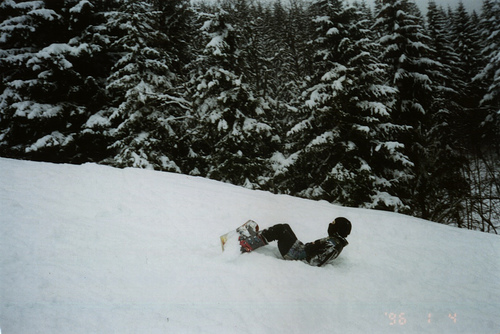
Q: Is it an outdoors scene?
A: Yes, it is outdoors.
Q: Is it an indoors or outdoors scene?
A: It is outdoors.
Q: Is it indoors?
A: No, it is outdoors.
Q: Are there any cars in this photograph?
A: No, there are no cars.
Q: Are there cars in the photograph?
A: No, there are no cars.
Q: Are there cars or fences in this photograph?
A: No, there are no cars or fences.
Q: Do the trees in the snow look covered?
A: Yes, the trees are covered.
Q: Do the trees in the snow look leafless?
A: No, the trees are covered.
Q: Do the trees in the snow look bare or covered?
A: The trees are covered.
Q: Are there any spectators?
A: No, there are no spectators.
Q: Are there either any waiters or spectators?
A: No, there are no spectators or waiters.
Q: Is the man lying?
A: Yes, the man is lying.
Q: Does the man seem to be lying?
A: Yes, the man is lying.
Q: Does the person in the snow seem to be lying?
A: Yes, the man is lying.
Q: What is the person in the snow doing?
A: The man is lying.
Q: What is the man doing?
A: The man is lying.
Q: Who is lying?
A: The man is lying.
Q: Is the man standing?
A: No, the man is lying.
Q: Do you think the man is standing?
A: No, the man is lying.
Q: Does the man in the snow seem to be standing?
A: No, the man is lying.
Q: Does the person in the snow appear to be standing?
A: No, the man is lying.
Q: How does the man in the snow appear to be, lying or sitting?
A: The man is lying.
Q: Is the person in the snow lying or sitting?
A: The man is lying.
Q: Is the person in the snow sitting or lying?
A: The man is lying.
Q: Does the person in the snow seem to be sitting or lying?
A: The man is lying.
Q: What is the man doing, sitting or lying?
A: The man is lying.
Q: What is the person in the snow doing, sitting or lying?
A: The man is lying.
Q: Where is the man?
A: The man is in the snow.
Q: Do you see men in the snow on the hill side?
A: Yes, there is a man in the snow.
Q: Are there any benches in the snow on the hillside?
A: No, there is a man in the snow.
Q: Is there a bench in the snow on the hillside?
A: No, there is a man in the snow.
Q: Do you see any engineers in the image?
A: No, there are no engineers.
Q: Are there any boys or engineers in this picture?
A: No, there are no engineers or boys.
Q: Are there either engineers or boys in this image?
A: No, there are no engineers or boys.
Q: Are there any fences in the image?
A: No, there are no fences.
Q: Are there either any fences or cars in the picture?
A: No, there are no fences or cars.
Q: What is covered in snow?
A: The tree is covered in snow.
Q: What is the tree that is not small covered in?
A: The tree is covered in snow.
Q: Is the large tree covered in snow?
A: Yes, the tree is covered in snow.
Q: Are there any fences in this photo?
A: No, there are no fences.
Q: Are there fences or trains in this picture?
A: No, there are no fences or trains.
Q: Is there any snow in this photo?
A: Yes, there is snow.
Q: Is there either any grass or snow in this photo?
A: Yes, there is snow.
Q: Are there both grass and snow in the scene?
A: No, there is snow but no grass.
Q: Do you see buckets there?
A: No, there are no buckets.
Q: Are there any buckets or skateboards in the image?
A: No, there are no buckets or skateboards.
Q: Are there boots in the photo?
A: Yes, there are boots.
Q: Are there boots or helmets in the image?
A: Yes, there are boots.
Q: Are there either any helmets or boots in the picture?
A: Yes, there are boots.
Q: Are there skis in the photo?
A: Yes, there are skis.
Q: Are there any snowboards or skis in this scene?
A: Yes, there are skis.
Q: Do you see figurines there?
A: No, there are no figurines.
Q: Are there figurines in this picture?
A: No, there are no figurines.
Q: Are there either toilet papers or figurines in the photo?
A: No, there are no figurines or toilet papers.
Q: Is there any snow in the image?
A: Yes, there is snow.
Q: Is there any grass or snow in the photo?
A: Yes, there is snow.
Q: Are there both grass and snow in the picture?
A: No, there is snow but no grass.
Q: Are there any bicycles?
A: No, there are no bicycles.